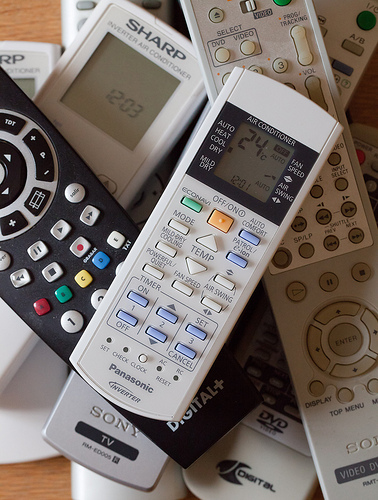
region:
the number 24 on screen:
[238, 122, 267, 162]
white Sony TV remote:
[68, 404, 146, 467]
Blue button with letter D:
[91, 243, 110, 270]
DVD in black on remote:
[258, 407, 292, 437]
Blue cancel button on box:
[169, 336, 197, 370]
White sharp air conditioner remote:
[119, 9, 191, 80]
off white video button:
[232, 29, 262, 57]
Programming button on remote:
[284, 13, 325, 68]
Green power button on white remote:
[350, 9, 377, 33]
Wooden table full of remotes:
[6, 6, 57, 38]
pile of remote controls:
[1, 0, 376, 499]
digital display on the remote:
[188, 88, 318, 221]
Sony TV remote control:
[43, 382, 170, 491]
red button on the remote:
[24, 289, 54, 319]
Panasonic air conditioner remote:
[56, 64, 345, 427]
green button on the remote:
[48, 286, 76, 306]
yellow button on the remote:
[71, 267, 93, 289]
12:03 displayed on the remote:
[97, 77, 146, 122]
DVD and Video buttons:
[202, 31, 265, 65]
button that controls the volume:
[300, 71, 325, 99]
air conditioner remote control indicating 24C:
[212, 121, 294, 205]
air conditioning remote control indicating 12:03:
[58, 29, 179, 150]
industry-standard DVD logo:
[255, 406, 287, 434]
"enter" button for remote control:
[325, 322, 364, 357]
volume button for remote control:
[304, 74, 328, 115]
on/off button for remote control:
[357, 10, 375, 29]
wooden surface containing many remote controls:
[0, 0, 377, 498]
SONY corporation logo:
[88, 404, 141, 438]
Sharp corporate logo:
[126, 17, 185, 61]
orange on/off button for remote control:
[208, 208, 235, 234]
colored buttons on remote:
[33, 252, 109, 315]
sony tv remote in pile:
[41, 369, 168, 490]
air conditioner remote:
[186, 101, 319, 228]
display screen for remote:
[186, 101, 319, 227]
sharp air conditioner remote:
[34, 0, 206, 206]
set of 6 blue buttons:
[115, 289, 206, 360]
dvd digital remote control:
[180, 399, 320, 498]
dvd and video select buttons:
[207, 27, 263, 66]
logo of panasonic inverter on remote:
[78, 343, 187, 413]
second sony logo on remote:
[322, 429, 376, 497]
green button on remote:
[178, 195, 202, 213]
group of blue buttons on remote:
[114, 289, 207, 360]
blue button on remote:
[88, 249, 110, 269]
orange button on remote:
[206, 205, 234, 232]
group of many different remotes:
[0, 0, 376, 497]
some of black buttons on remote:
[0, 108, 58, 236]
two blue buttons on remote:
[225, 226, 259, 268]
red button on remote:
[31, 295, 52, 315]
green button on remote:
[54, 284, 72, 302]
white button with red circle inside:
[67, 235, 90, 256]